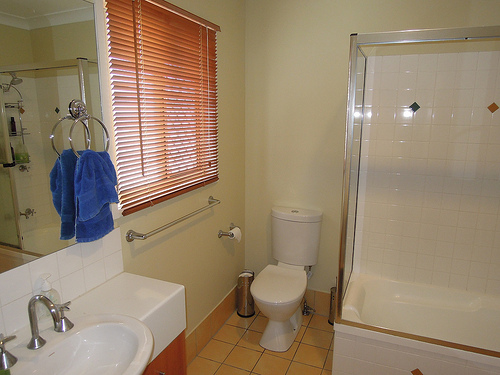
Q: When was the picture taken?
A: During the day.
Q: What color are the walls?
A: Creme.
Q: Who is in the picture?
A: No one.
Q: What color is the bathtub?
A: White.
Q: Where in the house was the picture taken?
A: The bathroom.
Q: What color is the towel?
A: Blue.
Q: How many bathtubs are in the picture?
A: One.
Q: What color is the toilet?
A: White.